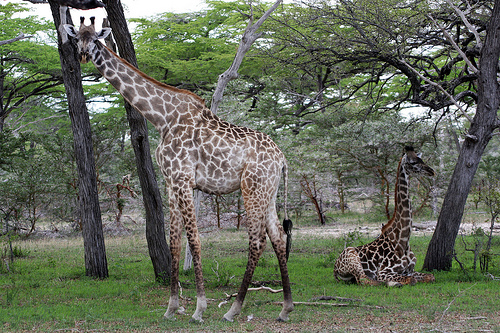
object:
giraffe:
[63, 16, 294, 324]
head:
[62, 16, 110, 65]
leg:
[221, 167, 274, 321]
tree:
[48, 2, 110, 277]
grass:
[2, 275, 117, 332]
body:
[155, 116, 286, 194]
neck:
[95, 51, 170, 120]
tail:
[282, 167, 292, 262]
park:
[2, 208, 495, 330]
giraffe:
[336, 144, 436, 288]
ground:
[382, 294, 495, 330]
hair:
[79, 27, 96, 37]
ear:
[99, 23, 112, 42]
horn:
[90, 18, 95, 27]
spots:
[218, 139, 229, 151]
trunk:
[423, 3, 497, 269]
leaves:
[159, 37, 207, 77]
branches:
[210, 0, 293, 121]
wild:
[6, 208, 494, 252]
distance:
[339, 178, 376, 207]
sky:
[140, 2, 190, 10]